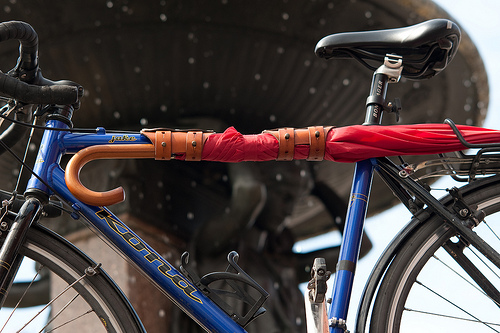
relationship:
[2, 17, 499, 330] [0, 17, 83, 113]
bike has black handlebar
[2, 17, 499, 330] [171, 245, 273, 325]
bike has holder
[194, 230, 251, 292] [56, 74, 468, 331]
pedal on bicycle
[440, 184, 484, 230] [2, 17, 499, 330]
brake on bike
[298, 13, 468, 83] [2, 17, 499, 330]
seat on bike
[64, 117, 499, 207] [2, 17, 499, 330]
umbrella attached to bike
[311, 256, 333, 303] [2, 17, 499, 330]
peddle on bike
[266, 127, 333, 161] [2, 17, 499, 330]
straps on bike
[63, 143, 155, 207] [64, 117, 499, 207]
holder of umbrella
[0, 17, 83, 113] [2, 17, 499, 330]
black handlebar of bike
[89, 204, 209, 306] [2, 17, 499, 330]
black letters on bike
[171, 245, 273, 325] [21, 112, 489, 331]
holder attached to frame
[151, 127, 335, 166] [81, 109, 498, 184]
belt around umbrella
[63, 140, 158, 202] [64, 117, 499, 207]
handle of umbrella